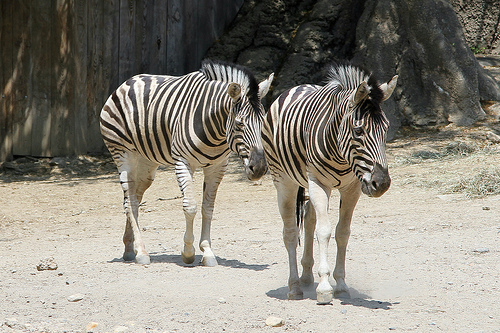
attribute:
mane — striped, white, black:
[202, 59, 268, 108]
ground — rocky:
[25, 163, 110, 323]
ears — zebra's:
[352, 74, 406, 111]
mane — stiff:
[323, 63, 392, 103]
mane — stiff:
[326, 62, 387, 102]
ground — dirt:
[16, 177, 473, 312]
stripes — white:
[134, 78, 224, 163]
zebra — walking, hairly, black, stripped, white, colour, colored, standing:
[265, 51, 398, 306]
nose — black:
[372, 166, 391, 198]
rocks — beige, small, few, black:
[35, 249, 72, 299]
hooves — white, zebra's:
[318, 287, 349, 306]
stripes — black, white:
[195, 106, 216, 145]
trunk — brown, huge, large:
[214, 1, 496, 102]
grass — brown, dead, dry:
[424, 137, 499, 207]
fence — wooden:
[0, 0, 196, 179]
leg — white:
[334, 192, 356, 294]